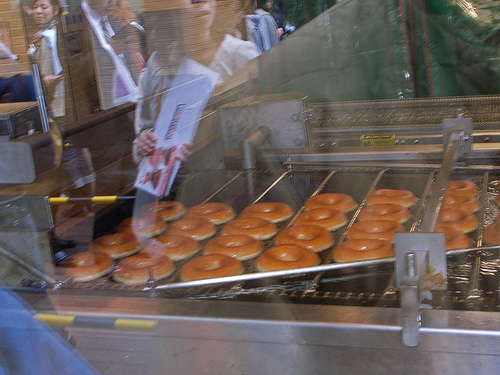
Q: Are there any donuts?
A: Yes, there is a donut.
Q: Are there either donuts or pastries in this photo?
A: Yes, there is a donut.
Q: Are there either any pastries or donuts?
A: Yes, there is a donut.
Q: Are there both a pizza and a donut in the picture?
A: No, there is a donut but no pizzas.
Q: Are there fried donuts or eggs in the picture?
A: Yes, there is a fried donut.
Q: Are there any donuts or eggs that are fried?
A: Yes, the donut is fried.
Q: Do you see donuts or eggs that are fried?
A: Yes, the donut is fried.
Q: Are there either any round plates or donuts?
A: Yes, there is a round donut.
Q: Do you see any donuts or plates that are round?
A: Yes, the donut is round.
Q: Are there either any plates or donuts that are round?
A: Yes, the donut is round.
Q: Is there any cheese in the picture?
A: No, there is no cheese.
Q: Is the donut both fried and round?
A: Yes, the donut is fried and round.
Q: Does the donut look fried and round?
A: Yes, the donut is fried and round.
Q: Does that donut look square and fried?
A: No, the donut is fried but round.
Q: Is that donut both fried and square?
A: No, the donut is fried but round.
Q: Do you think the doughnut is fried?
A: Yes, the doughnut is fried.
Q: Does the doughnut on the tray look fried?
A: Yes, the donut is fried.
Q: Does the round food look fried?
A: Yes, the donut is fried.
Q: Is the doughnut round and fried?
A: Yes, the doughnut is round and fried.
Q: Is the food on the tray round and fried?
A: Yes, the doughnut is round and fried.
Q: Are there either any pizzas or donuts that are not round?
A: No, there is a donut but it is round.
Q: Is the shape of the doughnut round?
A: Yes, the doughnut is round.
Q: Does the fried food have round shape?
A: Yes, the donut is round.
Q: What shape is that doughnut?
A: The doughnut is round.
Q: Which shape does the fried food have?
A: The doughnut has round shape.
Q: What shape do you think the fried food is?
A: The doughnut is round.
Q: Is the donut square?
A: No, the donut is round.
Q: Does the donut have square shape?
A: No, the donut is round.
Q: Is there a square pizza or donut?
A: No, there is a donut but it is round.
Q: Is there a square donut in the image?
A: No, there is a donut but it is round.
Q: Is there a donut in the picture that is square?
A: No, there is a donut but it is round.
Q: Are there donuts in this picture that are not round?
A: No, there is a donut but it is round.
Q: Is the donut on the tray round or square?
A: The doughnut is round.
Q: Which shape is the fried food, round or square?
A: The doughnut is round.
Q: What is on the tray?
A: The doughnut is on the tray.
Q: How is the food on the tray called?
A: The food is a donut.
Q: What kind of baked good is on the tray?
A: The food is a donut.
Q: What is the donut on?
A: The donut is on the tray.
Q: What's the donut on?
A: The donut is on the tray.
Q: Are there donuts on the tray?
A: Yes, there is a donut on the tray.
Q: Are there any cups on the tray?
A: No, there is a donut on the tray.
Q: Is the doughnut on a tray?
A: Yes, the doughnut is on a tray.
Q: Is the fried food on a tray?
A: Yes, the doughnut is on a tray.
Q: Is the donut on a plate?
A: No, the donut is on a tray.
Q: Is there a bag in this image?
A: No, there are no bags.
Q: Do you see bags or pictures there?
A: No, there are no bags or pictures.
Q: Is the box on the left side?
A: Yes, the box is on the left of the image.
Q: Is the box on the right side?
A: No, the box is on the left of the image.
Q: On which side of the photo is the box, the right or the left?
A: The box is on the left of the image.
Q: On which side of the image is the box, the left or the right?
A: The box is on the left of the image.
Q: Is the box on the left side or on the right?
A: The box is on the left of the image.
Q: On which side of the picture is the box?
A: The box is on the left of the image.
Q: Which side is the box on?
A: The box is on the left of the image.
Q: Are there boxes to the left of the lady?
A: Yes, there is a box to the left of the lady.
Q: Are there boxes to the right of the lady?
A: No, the box is to the left of the lady.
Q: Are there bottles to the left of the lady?
A: No, there is a box to the left of the lady.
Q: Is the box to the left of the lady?
A: Yes, the box is to the left of the lady.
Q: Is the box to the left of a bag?
A: No, the box is to the left of the lady.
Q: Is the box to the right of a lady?
A: No, the box is to the left of a lady.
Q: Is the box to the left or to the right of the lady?
A: The box is to the left of the lady.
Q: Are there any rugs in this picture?
A: No, there are no rugs.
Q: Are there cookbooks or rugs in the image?
A: No, there are no rugs or cookbooks.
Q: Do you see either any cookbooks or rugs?
A: No, there are no rugs or cookbooks.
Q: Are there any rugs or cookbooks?
A: No, there are no rugs or cookbooks.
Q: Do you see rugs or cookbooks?
A: No, there are no rugs or cookbooks.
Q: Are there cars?
A: No, there are no cars.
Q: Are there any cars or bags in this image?
A: No, there are no cars or bags.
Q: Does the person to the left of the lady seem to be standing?
A: Yes, the person is standing.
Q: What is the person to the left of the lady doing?
A: The person is standing.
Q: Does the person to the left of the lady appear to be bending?
A: No, the person is standing.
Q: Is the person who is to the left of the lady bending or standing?
A: The person is standing.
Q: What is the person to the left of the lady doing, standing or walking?
A: The person is standing.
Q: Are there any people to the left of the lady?
A: Yes, there is a person to the left of the lady.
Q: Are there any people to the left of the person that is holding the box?
A: Yes, there is a person to the left of the lady.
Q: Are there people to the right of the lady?
A: No, the person is to the left of the lady.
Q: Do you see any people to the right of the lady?
A: No, the person is to the left of the lady.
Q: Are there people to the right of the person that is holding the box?
A: No, the person is to the left of the lady.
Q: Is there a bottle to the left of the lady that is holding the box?
A: No, there is a person to the left of the lady.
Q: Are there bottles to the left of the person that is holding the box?
A: No, there is a person to the left of the lady.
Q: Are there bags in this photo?
A: No, there are no bags.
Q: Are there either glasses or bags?
A: No, there are no bags or glasses.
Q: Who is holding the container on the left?
A: The lady is holding the box.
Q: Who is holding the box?
A: The lady is holding the box.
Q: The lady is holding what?
A: The lady is holding the box.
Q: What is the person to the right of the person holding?
A: The lady is holding the box.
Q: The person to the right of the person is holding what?
A: The lady is holding the box.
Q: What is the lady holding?
A: The lady is holding the box.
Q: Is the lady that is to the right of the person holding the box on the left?
A: Yes, the lady is holding the box.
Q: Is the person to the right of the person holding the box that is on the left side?
A: Yes, the lady is holding the box.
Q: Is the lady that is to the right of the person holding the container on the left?
A: Yes, the lady is holding the box.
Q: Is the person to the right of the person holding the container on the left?
A: Yes, the lady is holding the box.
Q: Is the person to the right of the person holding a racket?
A: No, the lady is holding the box.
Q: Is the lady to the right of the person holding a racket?
A: No, the lady is holding the box.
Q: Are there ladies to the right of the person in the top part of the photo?
A: Yes, there is a lady to the right of the person.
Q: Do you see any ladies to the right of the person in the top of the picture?
A: Yes, there is a lady to the right of the person.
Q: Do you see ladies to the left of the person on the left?
A: No, the lady is to the right of the person.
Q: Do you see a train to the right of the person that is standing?
A: No, there is a lady to the right of the person.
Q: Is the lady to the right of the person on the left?
A: Yes, the lady is to the right of the person.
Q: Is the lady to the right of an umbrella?
A: No, the lady is to the right of the person.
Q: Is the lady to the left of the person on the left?
A: No, the lady is to the right of the person.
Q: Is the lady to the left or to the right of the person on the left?
A: The lady is to the right of the person.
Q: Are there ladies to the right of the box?
A: Yes, there is a lady to the right of the box.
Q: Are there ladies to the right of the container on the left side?
A: Yes, there is a lady to the right of the box.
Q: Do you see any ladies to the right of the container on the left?
A: Yes, there is a lady to the right of the box.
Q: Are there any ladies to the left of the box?
A: No, the lady is to the right of the box.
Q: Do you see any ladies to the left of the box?
A: No, the lady is to the right of the box.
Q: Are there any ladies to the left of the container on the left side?
A: No, the lady is to the right of the box.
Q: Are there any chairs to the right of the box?
A: No, there is a lady to the right of the box.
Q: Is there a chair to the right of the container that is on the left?
A: No, there is a lady to the right of the box.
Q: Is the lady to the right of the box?
A: Yes, the lady is to the right of the box.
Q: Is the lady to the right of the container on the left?
A: Yes, the lady is to the right of the box.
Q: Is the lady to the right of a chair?
A: No, the lady is to the right of the box.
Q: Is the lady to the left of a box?
A: No, the lady is to the right of a box.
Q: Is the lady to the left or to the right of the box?
A: The lady is to the right of the box.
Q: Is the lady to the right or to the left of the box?
A: The lady is to the right of the box.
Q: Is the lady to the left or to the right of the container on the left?
A: The lady is to the right of the box.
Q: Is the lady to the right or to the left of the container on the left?
A: The lady is to the right of the box.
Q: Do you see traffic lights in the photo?
A: No, there are no traffic lights.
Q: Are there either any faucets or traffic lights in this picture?
A: No, there are no traffic lights or faucets.